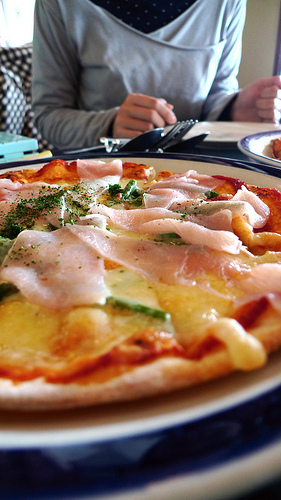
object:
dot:
[135, 5, 138, 7]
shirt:
[91, 0, 199, 34]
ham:
[0, 213, 106, 308]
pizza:
[0, 158, 281, 410]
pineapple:
[156, 273, 234, 334]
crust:
[0, 355, 189, 411]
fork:
[116, 119, 198, 153]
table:
[203, 117, 235, 133]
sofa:
[0, 41, 55, 155]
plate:
[0, 152, 281, 499]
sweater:
[30, 1, 248, 152]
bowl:
[236, 129, 281, 168]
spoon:
[62, 127, 164, 154]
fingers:
[113, 93, 177, 138]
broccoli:
[108, 178, 137, 205]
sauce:
[205, 193, 233, 200]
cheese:
[0, 265, 267, 372]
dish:
[204, 191, 218, 199]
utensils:
[61, 119, 211, 157]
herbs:
[106, 296, 170, 322]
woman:
[30, 1, 280, 152]